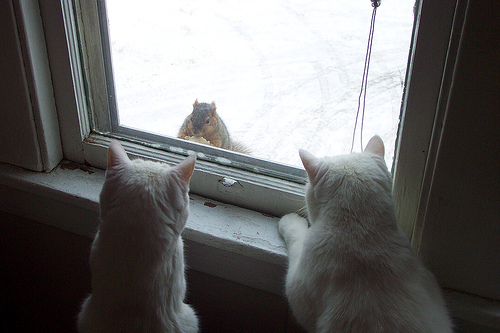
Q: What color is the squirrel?
A: Brown.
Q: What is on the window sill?
A: The cat's paw.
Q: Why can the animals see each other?
A: Because of the window.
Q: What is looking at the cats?
A: A squirrel.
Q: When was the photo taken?
A: Daylight.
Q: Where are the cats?
A: In the window.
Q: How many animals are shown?
A: Three.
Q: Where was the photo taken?
A: At a window in a home.